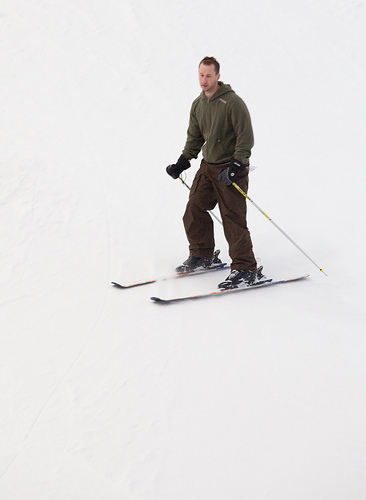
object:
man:
[164, 56, 258, 291]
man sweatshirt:
[179, 80, 253, 169]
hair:
[197, 55, 221, 76]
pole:
[229, 178, 327, 280]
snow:
[0, 0, 365, 499]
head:
[196, 58, 221, 92]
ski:
[109, 259, 227, 291]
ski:
[149, 270, 310, 304]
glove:
[165, 154, 194, 180]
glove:
[214, 158, 247, 187]